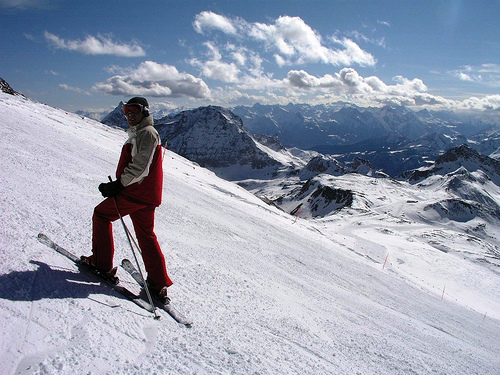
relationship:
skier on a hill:
[80, 97, 172, 306] [0, 76, 499, 374]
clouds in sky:
[25, 12, 500, 111] [0, 0, 499, 122]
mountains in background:
[100, 101, 499, 175] [99, 0, 499, 316]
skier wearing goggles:
[80, 97, 172, 306] [121, 103, 143, 115]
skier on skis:
[80, 97, 172, 306] [37, 232, 193, 325]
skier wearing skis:
[80, 97, 172, 306] [37, 232, 193, 325]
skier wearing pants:
[80, 97, 172, 306] [92, 193, 173, 295]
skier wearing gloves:
[80, 97, 172, 306] [99, 175, 126, 198]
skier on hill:
[80, 97, 172, 306] [0, 76, 499, 374]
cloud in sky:
[95, 59, 212, 101] [0, 0, 499, 122]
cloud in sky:
[192, 10, 375, 69] [0, 0, 499, 122]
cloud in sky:
[239, 68, 426, 97] [0, 0, 499, 122]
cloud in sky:
[43, 27, 147, 59] [0, 0, 499, 122]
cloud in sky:
[373, 93, 445, 109] [0, 0, 499, 122]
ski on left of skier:
[37, 233, 156, 312] [80, 97, 172, 306]